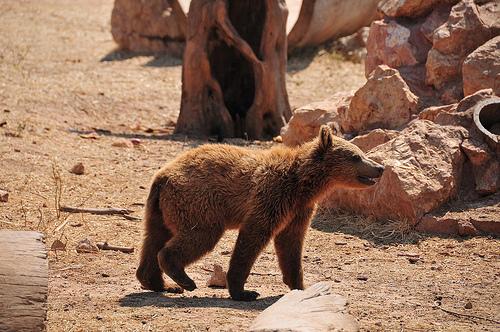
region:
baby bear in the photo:
[102, 125, 395, 301]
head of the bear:
[296, 113, 403, 208]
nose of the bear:
[361, 149, 394, 191]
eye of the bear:
[340, 141, 370, 171]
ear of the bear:
[303, 107, 347, 155]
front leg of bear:
[276, 212, 328, 290]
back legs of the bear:
[114, 201, 227, 303]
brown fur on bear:
[190, 151, 307, 210]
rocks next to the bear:
[356, 30, 476, 129]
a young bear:
[111, 121, 399, 301]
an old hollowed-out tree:
[164, 11, 299, 132]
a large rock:
[340, 60, 421, 132]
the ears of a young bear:
[312, 116, 347, 153]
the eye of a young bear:
[347, 149, 365, 165]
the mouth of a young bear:
[355, 171, 385, 193]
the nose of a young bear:
[370, 157, 392, 179]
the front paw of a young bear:
[217, 263, 267, 306]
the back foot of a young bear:
[152, 243, 208, 302]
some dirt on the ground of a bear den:
[24, 81, 127, 168]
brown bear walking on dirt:
[136, 119, 383, 299]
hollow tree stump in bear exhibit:
[173, 0, 295, 140]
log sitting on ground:
[0, 225, 45, 330]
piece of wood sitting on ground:
[249, 280, 358, 330]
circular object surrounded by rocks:
[472, 95, 499, 144]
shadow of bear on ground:
[118, 289, 283, 309]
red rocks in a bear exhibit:
[279, 0, 499, 236]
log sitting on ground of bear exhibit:
[110, 0, 186, 55]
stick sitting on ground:
[57, 205, 133, 211]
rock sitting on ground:
[204, 262, 226, 288]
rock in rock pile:
[339, 60, 421, 121]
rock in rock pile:
[272, 80, 355, 137]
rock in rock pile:
[353, 110, 461, 230]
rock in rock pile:
[361, 18, 418, 70]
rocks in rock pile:
[428, 2, 499, 99]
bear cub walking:
[138, 120, 393, 298]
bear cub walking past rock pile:
[130, 119, 385, 299]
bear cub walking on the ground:
[136, 116, 386, 294]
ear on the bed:
[320, 125, 335, 146]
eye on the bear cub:
[352, 155, 363, 165]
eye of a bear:
[350, 152, 361, 160]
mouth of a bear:
[348, 170, 382, 185]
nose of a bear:
[373, 162, 385, 173]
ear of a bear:
[314, 122, 335, 147]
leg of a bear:
[223, 197, 277, 302]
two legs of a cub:
[222, 205, 319, 301]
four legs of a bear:
[133, 204, 317, 301]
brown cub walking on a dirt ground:
[130, 117, 386, 303]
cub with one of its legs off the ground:
[131, 119, 386, 299]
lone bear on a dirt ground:
[135, 119, 390, 302]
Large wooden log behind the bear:
[24, 175, 71, 313]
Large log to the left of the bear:
[260, 64, 458, 277]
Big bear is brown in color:
[116, 122, 392, 297]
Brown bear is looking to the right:
[98, 105, 445, 312]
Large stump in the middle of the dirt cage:
[131, 22, 378, 146]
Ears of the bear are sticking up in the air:
[303, 101, 351, 201]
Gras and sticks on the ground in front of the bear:
[324, 216, 482, 316]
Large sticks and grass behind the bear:
[14, 102, 132, 308]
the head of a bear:
[299, 115, 384, 200]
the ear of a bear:
[310, 119, 343, 151]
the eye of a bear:
[344, 149, 364, 164]